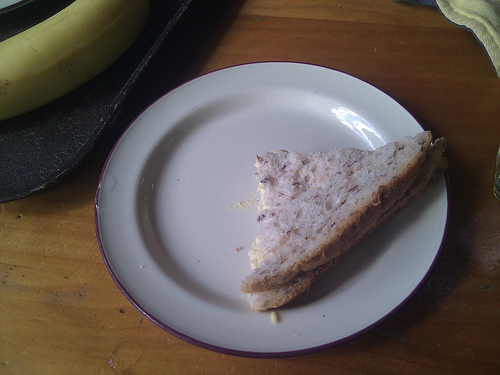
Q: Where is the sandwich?
A: On the plate.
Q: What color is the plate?
A: White.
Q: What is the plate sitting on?
A: The table.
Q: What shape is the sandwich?
A: Triangle.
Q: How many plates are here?
A: One.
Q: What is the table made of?
A: Wood.